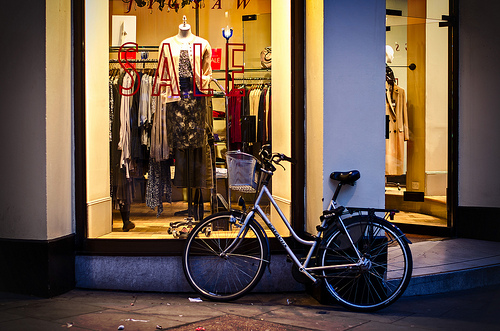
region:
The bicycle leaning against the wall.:
[176, 137, 412, 308]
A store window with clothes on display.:
[70, 3, 293, 246]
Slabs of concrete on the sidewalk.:
[5, 296, 373, 327]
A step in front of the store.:
[410, 260, 493, 296]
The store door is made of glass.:
[382, 11, 457, 234]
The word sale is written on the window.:
[111, 36, 247, 101]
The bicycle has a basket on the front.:
[220, 143, 257, 193]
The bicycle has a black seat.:
[330, 161, 360, 187]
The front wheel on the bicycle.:
[182, 206, 265, 301]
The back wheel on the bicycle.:
[314, 213, 411, 313]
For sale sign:
[109, 38, 251, 100]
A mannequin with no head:
[156, 13, 213, 236]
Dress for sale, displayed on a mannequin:
[152, 20, 219, 202]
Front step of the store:
[342, 235, 497, 313]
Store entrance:
[304, 0, 497, 329]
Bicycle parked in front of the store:
[175, 135, 415, 317]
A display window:
[68, 0, 308, 253]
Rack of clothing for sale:
[102, 50, 177, 233]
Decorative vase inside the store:
[254, 45, 273, 72]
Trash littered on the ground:
[48, 290, 359, 329]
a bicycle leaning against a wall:
[176, 133, 421, 313]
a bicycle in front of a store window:
[153, 128, 445, 325]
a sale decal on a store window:
[93, 35, 281, 116]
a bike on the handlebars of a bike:
[221, 144, 274, 195]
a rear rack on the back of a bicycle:
[343, 197, 412, 237]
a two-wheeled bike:
[176, 135, 449, 329]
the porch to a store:
[388, 17, 487, 288]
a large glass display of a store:
[55, 0, 286, 243]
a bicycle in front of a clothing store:
[61, 0, 480, 310]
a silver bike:
[156, 138, 438, 310]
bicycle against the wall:
[209, 155, 396, 308]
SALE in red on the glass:
[110, 27, 270, 97]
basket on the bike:
[218, 145, 257, 212]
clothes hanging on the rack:
[106, 56, 177, 157]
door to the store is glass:
[235, 8, 291, 81]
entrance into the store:
[385, 48, 499, 238]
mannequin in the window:
[158, 42, 232, 126]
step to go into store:
[442, 246, 477, 303]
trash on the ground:
[187, 284, 212, 308]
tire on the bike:
[177, 208, 261, 293]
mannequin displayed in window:
[156, 13, 213, 221]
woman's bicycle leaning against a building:
[180, 141, 414, 310]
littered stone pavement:
[2, 291, 460, 329]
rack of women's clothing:
[108, 43, 205, 218]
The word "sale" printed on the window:
[117, 39, 248, 99]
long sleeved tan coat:
[383, 80, 411, 177]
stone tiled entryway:
[387, 236, 497, 298]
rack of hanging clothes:
[228, 80, 272, 157]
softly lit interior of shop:
[109, 0, 271, 230]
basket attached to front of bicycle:
[223, 147, 256, 189]